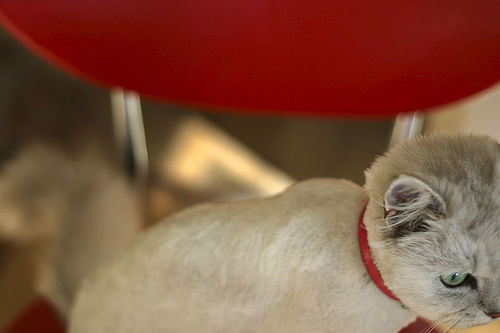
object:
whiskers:
[417, 306, 466, 331]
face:
[392, 225, 498, 331]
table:
[0, 0, 499, 184]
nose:
[478, 302, 499, 321]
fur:
[182, 204, 352, 291]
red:
[356, 197, 401, 304]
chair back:
[3, 0, 499, 117]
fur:
[424, 146, 481, 186]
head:
[360, 131, 499, 331]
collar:
[361, 205, 405, 307]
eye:
[437, 270, 473, 289]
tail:
[3, 138, 145, 319]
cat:
[68, 133, 500, 332]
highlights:
[170, 220, 467, 322]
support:
[113, 86, 158, 186]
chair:
[2, 0, 499, 226]